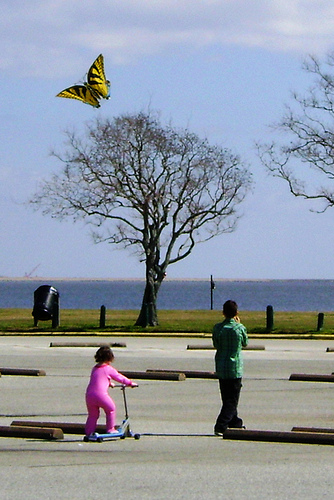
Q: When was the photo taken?
A: During the daytime.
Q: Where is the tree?
A: Next to the sidewalk.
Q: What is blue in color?
A: The sky.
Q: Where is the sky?
A: Above the water.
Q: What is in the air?
A: A butterfly kite.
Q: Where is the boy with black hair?
A: In the parking lot.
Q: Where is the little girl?
A: In the parking lot.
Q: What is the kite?
A: A butterfly.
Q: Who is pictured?
A: A young girl and boy.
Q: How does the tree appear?
A: No leaves.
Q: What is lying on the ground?
A: Many logs.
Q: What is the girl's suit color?
A: Pink.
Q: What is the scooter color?
A: Blue.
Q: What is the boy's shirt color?
A: Green.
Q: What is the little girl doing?
A: Riding a scooter.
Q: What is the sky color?
A: Blue with light clouds.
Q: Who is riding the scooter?
A: Girl.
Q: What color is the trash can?
A: Black.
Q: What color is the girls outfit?
A: Pink.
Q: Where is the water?
A: Behind the tree.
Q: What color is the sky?
A: Blue.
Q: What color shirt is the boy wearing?
A: Green.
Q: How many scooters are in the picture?
A: One.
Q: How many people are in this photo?
A: Two.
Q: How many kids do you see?
A: Two.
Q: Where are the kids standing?
A: In the parking lot.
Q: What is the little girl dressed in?
A: A pink suit.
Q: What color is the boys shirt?
A: Green.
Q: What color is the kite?
A: Black and yellow.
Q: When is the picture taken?
A: During the day.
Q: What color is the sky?
A: Blue.